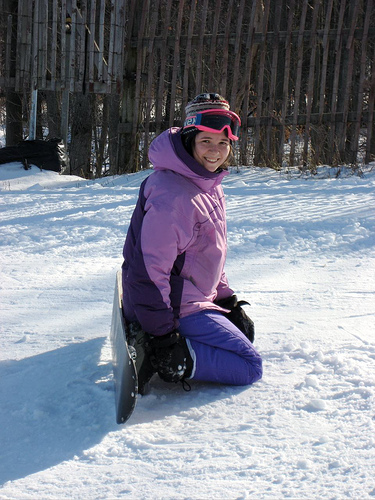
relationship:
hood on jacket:
[146, 127, 184, 168] [122, 129, 233, 313]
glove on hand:
[209, 289, 254, 340] [208, 288, 257, 341]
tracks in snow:
[0, 349, 368, 459] [2, 173, 365, 496]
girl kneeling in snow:
[112, 88, 263, 390] [274, 286, 355, 436]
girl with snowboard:
[112, 88, 263, 390] [105, 267, 142, 430]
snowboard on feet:
[105, 267, 142, 430] [122, 305, 170, 396]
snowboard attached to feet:
[104, 267, 142, 429] [135, 339, 179, 398]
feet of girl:
[135, 339, 179, 398] [112, 88, 263, 390]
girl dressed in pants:
[110, 88, 266, 392] [176, 309, 263, 384]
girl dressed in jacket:
[110, 88, 266, 392] [111, 124, 245, 344]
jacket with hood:
[111, 124, 245, 344] [139, 114, 231, 195]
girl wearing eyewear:
[112, 88, 263, 390] [196, 113, 242, 141]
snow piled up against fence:
[0, 159, 95, 193] [0, 0, 372, 177]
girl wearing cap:
[112, 88, 263, 390] [184, 91, 231, 114]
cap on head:
[184, 91, 231, 114] [181, 111, 231, 176]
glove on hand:
[153, 327, 193, 383] [151, 329, 187, 382]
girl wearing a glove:
[112, 88, 263, 390] [153, 327, 193, 383]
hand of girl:
[151, 329, 187, 382] [112, 88, 263, 390]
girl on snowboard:
[112, 88, 263, 390] [98, 270, 139, 423]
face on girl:
[172, 103, 241, 166] [82, 102, 274, 373]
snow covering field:
[16, 166, 367, 483] [0, 128, 362, 498]